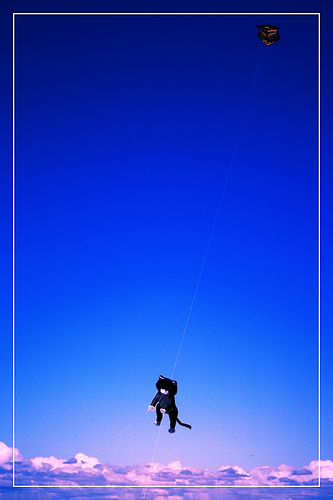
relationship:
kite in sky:
[258, 22, 282, 51] [3, 0, 324, 499]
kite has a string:
[258, 22, 282, 51] [172, 48, 260, 379]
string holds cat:
[172, 48, 260, 379] [150, 377, 194, 435]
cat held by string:
[150, 377, 194, 435] [172, 48, 260, 379]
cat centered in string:
[150, 377, 194, 435] [172, 48, 260, 379]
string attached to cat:
[172, 48, 260, 379] [150, 377, 194, 435]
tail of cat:
[175, 413, 193, 431] [150, 377, 194, 435]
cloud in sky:
[0, 440, 332, 499] [3, 0, 324, 499]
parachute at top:
[258, 22, 282, 51] [1, 4, 332, 141]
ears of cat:
[156, 375, 178, 385] [150, 377, 194, 435]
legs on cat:
[156, 406, 177, 431] [150, 377, 194, 435]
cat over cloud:
[150, 377, 194, 435] [0, 440, 332, 499]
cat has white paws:
[150, 377, 194, 435] [148, 404, 165, 415]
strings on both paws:
[81, 410, 167, 499] [148, 404, 165, 415]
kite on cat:
[258, 22, 282, 51] [150, 377, 194, 435]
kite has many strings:
[258, 22, 282, 51] [81, 410, 167, 499]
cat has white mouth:
[150, 377, 194, 435] [159, 385, 172, 397]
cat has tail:
[150, 377, 194, 435] [175, 413, 193, 431]